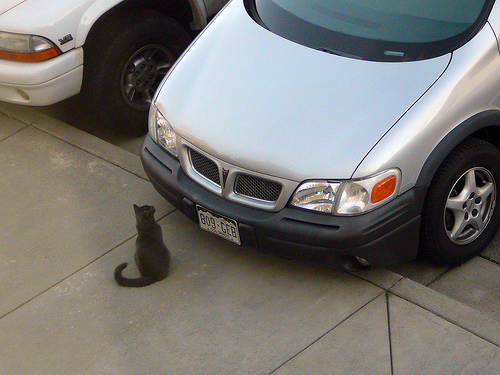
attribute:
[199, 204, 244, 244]
license plate — green, white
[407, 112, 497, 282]
tire — black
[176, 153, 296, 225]
grill — silver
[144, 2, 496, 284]
van — silver, pontiac van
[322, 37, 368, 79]
wiper — recessed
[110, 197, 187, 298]
cat — sitting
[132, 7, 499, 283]
car — plastic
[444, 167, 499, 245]
rim — silver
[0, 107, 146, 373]
sidewalk — concrete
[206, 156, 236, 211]
logo — red, pontiac logo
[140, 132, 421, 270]
bumper — gray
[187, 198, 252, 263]
license plate — colorado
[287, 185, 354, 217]
headlight — silver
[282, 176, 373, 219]
headlight — silver